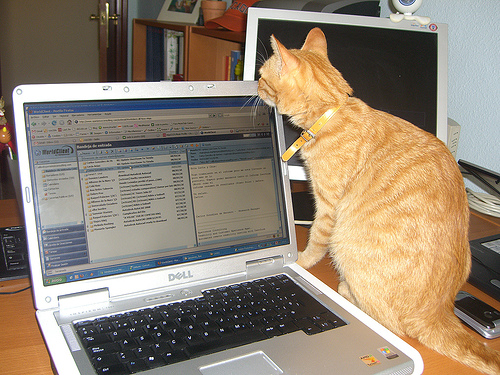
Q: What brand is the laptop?
A: Dell.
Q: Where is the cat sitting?
A: To the right of the laptop.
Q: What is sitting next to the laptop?
A: A cat.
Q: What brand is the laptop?
A: Dell.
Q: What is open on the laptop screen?
A: E-mail.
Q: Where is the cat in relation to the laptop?
A: To the right.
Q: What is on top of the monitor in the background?
A: A webcam.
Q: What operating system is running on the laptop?
A: Windows XP.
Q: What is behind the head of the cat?
A: A monitor.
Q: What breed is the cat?
A: Domestic Shorthair.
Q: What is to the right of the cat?
A: A cell phone.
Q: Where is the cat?
A: On a desk.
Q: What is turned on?
A: Computer screen.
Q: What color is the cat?
A: Orange.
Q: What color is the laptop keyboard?
A: Black.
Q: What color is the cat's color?
A: Yellow.